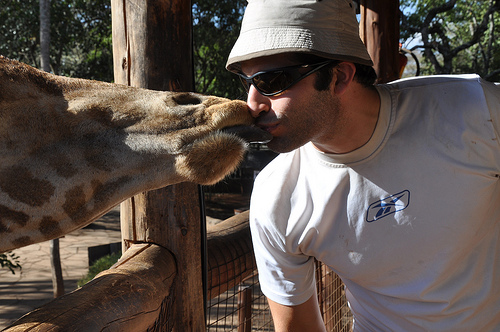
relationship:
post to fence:
[106, 2, 216, 330] [115, 208, 355, 325]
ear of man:
[332, 53, 369, 101] [235, 24, 482, 326]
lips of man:
[251, 115, 283, 136] [245, 0, 497, 327]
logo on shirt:
[367, 189, 410, 223] [229, 59, 499, 324]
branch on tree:
[421, 0, 498, 74] [399, 2, 498, 78]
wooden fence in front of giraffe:
[1, 208, 248, 330] [3, 57, 271, 250]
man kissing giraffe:
[245, 0, 497, 327] [4, 60, 279, 237]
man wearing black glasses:
[248, 0, 497, 332] [239, 59, 338, 96]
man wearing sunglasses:
[248, 0, 497, 332] [227, 53, 340, 97]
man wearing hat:
[248, 0, 497, 332] [222, 0, 377, 72]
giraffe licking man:
[0, 53, 251, 255] [245, 0, 497, 327]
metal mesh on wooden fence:
[208, 197, 263, 291] [190, 227, 289, 322]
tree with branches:
[389, 5, 499, 72] [421, 19, 443, 68]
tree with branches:
[389, 5, 499, 72] [452, 19, 499, 51]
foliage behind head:
[6, 3, 492, 181] [26, 36, 330, 245]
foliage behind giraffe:
[6, 3, 492, 181] [3, 57, 271, 250]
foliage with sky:
[165, 16, 252, 119] [0, 1, 499, 78]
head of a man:
[231, 0, 412, 161] [248, 0, 497, 332]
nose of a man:
[245, 87, 271, 122] [248, 0, 497, 332]